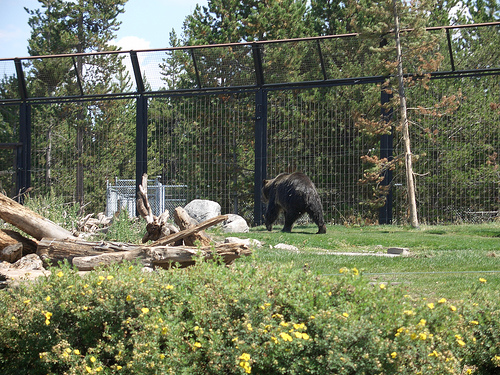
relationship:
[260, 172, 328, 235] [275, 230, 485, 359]
bear in field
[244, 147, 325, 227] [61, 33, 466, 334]
bear in zoo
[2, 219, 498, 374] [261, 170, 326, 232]
grass under bear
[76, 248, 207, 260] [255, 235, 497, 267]
logs on ground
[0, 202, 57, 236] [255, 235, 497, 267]
logs on ground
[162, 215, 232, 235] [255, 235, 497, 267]
logs on ground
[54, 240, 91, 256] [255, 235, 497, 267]
logs on ground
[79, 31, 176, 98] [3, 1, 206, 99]
cloud in sky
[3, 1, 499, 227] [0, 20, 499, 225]
trees passed fence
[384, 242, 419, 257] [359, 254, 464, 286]
small step on ground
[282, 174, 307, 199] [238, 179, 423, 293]
fur of bear